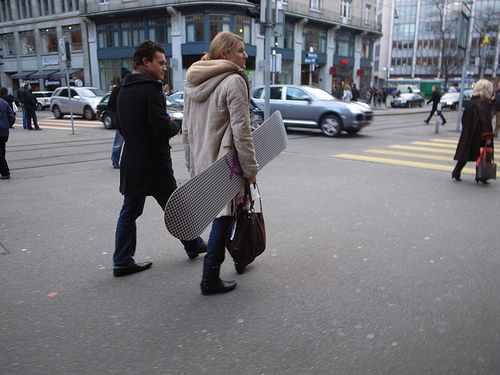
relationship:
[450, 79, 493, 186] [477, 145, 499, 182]
woman carrying brown bag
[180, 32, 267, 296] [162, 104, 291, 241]
people carrying board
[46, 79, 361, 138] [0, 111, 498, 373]
cars driving on street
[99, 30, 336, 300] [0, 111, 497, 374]
people walking on street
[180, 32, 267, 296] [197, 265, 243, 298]
people wearing boots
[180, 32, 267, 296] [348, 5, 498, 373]
people looking to right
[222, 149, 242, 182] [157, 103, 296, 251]
x on snowboard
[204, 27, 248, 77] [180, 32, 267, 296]
hair on people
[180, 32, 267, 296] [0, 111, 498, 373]
people walking on street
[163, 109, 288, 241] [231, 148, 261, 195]
snowboard in hand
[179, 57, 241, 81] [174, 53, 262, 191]
hood on back of coat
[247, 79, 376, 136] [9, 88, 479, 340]
car in intersection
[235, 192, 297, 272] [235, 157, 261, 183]
purse in hand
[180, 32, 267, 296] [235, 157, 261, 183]
people has hand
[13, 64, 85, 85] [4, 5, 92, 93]
awnings on side of building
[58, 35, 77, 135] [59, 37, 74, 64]
sign on pole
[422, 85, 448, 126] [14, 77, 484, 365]
man walking across on street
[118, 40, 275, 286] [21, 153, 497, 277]
couple walking down street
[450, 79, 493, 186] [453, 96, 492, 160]
woman wearing coat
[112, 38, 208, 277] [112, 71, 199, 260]
man wearing clothing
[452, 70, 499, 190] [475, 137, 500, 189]
woman with bags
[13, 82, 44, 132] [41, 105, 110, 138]
people waiting to cross street